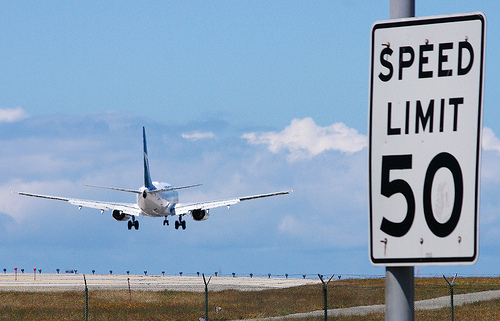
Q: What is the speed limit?
A: 50.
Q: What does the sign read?
A: Speed limit 50.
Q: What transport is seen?
A: Plane.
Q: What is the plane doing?
A: Landing.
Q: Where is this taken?
A: Airport runway.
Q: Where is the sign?
A: Silver pole.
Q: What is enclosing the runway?
A: Metal fence.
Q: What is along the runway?
A: Dried grass.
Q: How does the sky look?
A: Blue with clouds.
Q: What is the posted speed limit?
A: 50 MPH.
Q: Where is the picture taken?
A: An airport.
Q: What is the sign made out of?
A: Metal.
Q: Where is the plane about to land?
A: Runway.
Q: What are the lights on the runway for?
A: Guide the plane.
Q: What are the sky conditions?
A: Partially cloudy.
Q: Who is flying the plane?
A: Pilot.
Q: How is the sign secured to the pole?
A: Metal bolts.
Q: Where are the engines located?
A: Below both wings.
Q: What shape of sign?
A: Rectangular.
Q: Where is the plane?
A: In the sky.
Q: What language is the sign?
A: English.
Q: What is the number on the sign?
A: 50.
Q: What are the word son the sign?
A: Speed Limit.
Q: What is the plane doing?
A: Taking off.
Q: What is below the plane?
A: The tarmac.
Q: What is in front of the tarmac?
A: Barbed wire fencing.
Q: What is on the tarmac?
A: Reflective lights.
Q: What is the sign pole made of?
A: Metal.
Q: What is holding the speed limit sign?
A: A metal pole.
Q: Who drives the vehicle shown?
A: Pilot.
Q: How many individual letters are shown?
A: Ten.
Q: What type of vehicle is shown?
A: Plane.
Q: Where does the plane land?
A: Runway.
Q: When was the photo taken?
A: Daytime.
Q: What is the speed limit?
A: 50.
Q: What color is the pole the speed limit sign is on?
A: Grey.